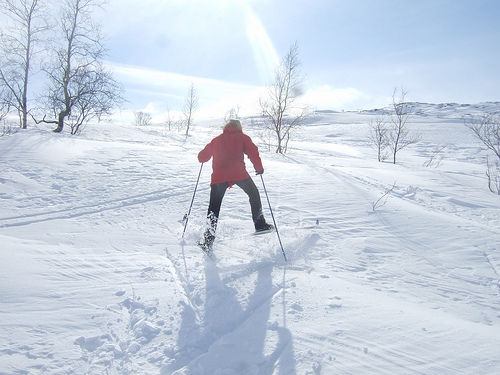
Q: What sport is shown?
A: Skiing.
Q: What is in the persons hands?
A: Ski poles.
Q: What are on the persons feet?
A: Skis.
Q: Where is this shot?
A: Mountain.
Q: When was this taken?
A: Daytime.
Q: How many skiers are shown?
A: 1.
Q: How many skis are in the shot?
A: 2.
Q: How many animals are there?
A: 0.